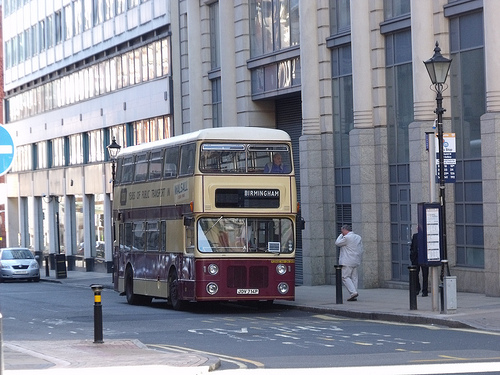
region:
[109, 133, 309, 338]
This is a bus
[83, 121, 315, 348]
This is a double decker bus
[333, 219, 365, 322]
This is a person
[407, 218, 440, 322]
This is a person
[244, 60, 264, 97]
Window of a house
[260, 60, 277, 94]
Window of a house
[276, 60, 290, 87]
Window of a house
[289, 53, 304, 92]
Window of a house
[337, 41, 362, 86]
Window of a house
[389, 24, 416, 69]
Window of a house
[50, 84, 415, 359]
the bus is a double decker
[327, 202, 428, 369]
the man is wearing a white suit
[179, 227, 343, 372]
the bottom of the bus is red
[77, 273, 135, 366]
the pole has a yellow sticker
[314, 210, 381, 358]
the man is walking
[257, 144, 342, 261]
the man is reiding hte bus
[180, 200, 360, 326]
the windows are large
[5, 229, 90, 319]
the car is silver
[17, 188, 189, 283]
windows are on the building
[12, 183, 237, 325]
the windows are long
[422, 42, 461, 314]
lamppost on the street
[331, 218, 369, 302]
man wearing white walking on the street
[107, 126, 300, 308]
a double decker bus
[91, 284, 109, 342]
a small black pole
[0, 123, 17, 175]
a light blue sign on the street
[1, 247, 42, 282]
a grey car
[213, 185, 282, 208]
a black rectangle on the bus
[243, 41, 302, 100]
grey window on the building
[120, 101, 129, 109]
grey square on the building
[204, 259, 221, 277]
headlamp on the bus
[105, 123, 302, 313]
The bus is double decker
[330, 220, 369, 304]
Man wearing a white suit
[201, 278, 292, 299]
Two headlights are round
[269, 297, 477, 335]
The curb of a sidewalk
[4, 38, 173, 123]
A row of windows on the building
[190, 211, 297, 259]
Front window of a bus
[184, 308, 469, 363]
White markings on the road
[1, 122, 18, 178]
The side of a blue and white sign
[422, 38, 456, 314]
A tall black street lamp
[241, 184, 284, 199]
"BIRMINGHAM" written on front of bus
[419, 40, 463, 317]
metal lamp with post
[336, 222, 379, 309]
a person walking in the side walk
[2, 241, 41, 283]
a car parked in the parking area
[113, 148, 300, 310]
a bus parked in the road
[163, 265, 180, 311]
wheel of the bus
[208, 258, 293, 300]
head light in front of the bus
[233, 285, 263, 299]
white color number plate of the bus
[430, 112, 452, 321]
black color coated metal post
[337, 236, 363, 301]
a person wearing white color dress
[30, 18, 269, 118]
big building with lot of windows